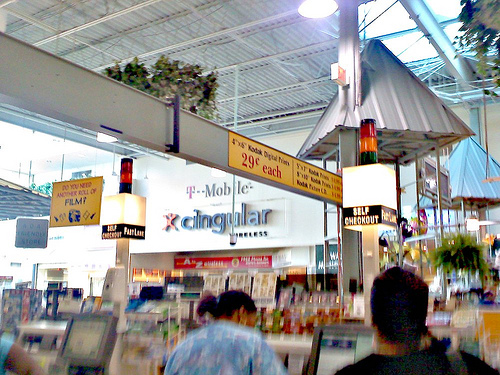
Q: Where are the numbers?
A: On sign.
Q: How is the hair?
A: Ponytail.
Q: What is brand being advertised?
A: Kodak.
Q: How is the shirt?
A: Colorful.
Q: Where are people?
A: Mall.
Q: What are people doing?
A: Shopping.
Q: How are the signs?
A: Hanging.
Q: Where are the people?
A: In store.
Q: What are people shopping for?
A: Cell phones.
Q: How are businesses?
A: Open.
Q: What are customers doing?
A: Purchasing.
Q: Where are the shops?
A: In mall.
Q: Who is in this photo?
A: Two people.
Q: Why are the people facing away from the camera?
A: They are checking out.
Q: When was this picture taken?
A: Daytime.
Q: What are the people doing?
A: Paying.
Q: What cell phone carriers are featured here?
A: T Mobile & Cingular.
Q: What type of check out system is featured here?
A: Self checkout.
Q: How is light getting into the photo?
A: A skylight.